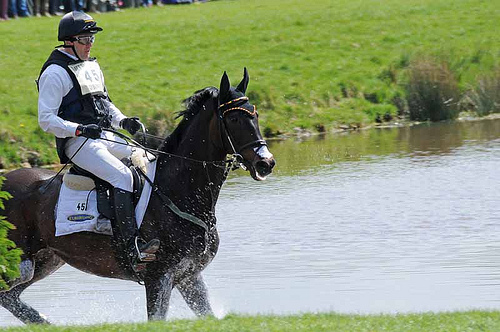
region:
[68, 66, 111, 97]
45 on the man's chest.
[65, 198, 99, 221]
45 on the horse.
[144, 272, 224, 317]
The water is splashing.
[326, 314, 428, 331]
The grass is green.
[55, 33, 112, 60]
The man is wearing goggles.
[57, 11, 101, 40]
The man is wearing a helmet.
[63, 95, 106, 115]
The vest is black.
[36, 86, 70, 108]
The shirt is white.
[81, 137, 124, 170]
The pants are white.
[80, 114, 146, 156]
The gloves are black.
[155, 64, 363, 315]
A horse is visible.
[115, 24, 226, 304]
A horse is visible.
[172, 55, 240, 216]
A horse is visible.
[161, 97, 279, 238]
A horse is visible.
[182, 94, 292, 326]
A horse is visible.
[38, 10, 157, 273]
a horse jockey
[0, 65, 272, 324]
a racing horse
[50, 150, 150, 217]
a horse saddle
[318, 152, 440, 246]
a body of water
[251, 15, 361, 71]
a field of green grass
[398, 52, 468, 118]
a bush on the edge of the water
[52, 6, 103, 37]
a horse riding helmet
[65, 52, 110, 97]
a bib displaying the competitor's number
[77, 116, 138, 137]
riding gloves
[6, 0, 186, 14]
spectator's feet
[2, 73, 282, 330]
a dark brown horse is walking on grass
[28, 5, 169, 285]
a man riding a horse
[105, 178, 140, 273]
man wearing black boots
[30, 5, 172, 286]
a wearing a black hat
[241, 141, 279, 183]
the muzzle of the horse is black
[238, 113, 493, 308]
a horse passing through a river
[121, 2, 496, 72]
a field of green grass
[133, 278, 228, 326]
front legs of horse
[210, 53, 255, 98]
the ears of horse are pointy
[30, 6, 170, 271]
man has a vest with number 45